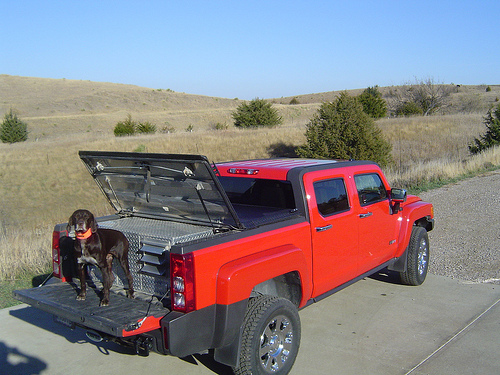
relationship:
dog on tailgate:
[67, 213, 136, 298] [13, 280, 169, 341]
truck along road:
[23, 152, 435, 373] [365, 174, 483, 374]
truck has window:
[23, 152, 435, 373] [219, 174, 299, 214]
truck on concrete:
[23, 152, 435, 373] [323, 289, 479, 364]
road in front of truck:
[365, 174, 483, 374] [23, 152, 435, 373]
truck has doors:
[23, 152, 435, 373] [312, 166, 391, 296]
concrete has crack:
[323, 289, 479, 364] [403, 295, 495, 369]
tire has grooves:
[242, 294, 300, 374] [253, 300, 273, 311]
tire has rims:
[242, 294, 300, 374] [260, 315, 295, 371]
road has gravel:
[365, 174, 483, 374] [444, 199, 484, 248]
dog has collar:
[67, 213, 136, 298] [71, 229, 96, 240]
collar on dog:
[71, 229, 96, 240] [67, 213, 136, 298]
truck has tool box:
[23, 152, 435, 373] [103, 218, 210, 300]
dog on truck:
[67, 213, 136, 298] [23, 152, 435, 373]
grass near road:
[55, 95, 101, 144] [365, 174, 483, 374]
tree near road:
[309, 94, 388, 161] [365, 174, 483, 374]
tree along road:
[309, 94, 388, 161] [365, 174, 483, 374]